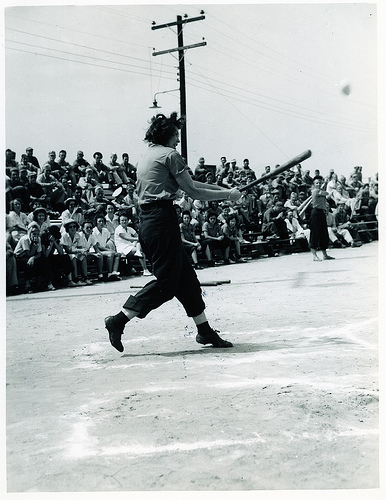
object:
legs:
[141, 222, 209, 324]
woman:
[104, 112, 241, 352]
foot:
[195, 321, 235, 348]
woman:
[307, 173, 336, 265]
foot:
[102, 314, 128, 355]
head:
[145, 109, 188, 147]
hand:
[227, 182, 245, 207]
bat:
[229, 145, 314, 202]